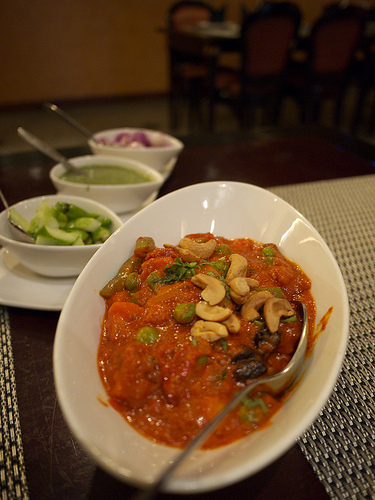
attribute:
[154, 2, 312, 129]
table — in background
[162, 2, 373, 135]
chairs — in background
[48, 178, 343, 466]
bowl — white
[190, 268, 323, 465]
spoon — silvertone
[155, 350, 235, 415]
sauce — red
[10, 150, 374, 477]
table — brown, wooden, surface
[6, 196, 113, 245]
apples — green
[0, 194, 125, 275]
bowl — white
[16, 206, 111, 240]
chunks — green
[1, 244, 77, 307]
plate — white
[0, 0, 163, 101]
wall — light brown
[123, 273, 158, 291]
peas — green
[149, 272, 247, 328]
dish — tomato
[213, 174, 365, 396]
mat — woven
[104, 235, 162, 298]
vegetables — green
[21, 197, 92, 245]
apples — green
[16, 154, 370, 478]
bowl — white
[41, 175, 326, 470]
dish — main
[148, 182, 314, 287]
dish — white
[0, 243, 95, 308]
dish — white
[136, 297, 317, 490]
spoon — silver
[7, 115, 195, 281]
containers — small, white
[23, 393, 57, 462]
counter — marble, granite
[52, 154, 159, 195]
sauce — green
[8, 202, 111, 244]
veggies — green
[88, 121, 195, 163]
bowl — white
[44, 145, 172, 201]
bowl — white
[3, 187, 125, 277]
bowl — white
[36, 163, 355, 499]
bowl — white, oval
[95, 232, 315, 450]
sauce — red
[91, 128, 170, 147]
something — purple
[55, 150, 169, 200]
sauce — green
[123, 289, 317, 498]
spoon — silver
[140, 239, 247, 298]
stuff — green, leafy, on top